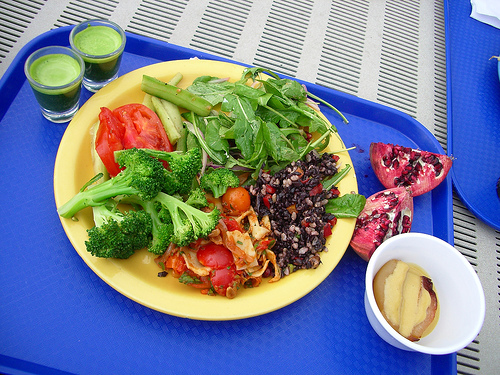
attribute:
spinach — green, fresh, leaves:
[180, 66, 365, 218]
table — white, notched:
[2, 1, 499, 372]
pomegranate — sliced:
[350, 184, 412, 261]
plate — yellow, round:
[52, 58, 358, 321]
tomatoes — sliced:
[94, 103, 171, 175]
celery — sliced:
[138, 72, 212, 142]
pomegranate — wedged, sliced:
[371, 140, 453, 195]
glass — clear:
[23, 44, 86, 124]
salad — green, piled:
[175, 65, 365, 215]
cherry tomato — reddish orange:
[222, 185, 250, 215]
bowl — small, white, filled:
[363, 230, 483, 353]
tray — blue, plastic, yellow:
[1, 23, 457, 373]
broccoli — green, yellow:
[56, 147, 239, 257]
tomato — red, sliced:
[95, 102, 173, 177]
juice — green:
[27, 56, 82, 100]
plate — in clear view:
[58, 77, 360, 332]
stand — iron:
[29, 4, 439, 86]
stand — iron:
[28, 7, 439, 67]